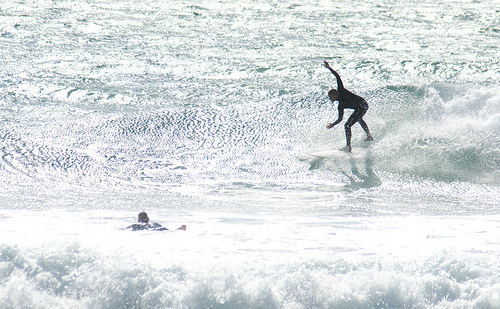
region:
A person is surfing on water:
[277, 35, 412, 166]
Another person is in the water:
[111, 195, 196, 255]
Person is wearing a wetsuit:
[295, 55, 400, 180]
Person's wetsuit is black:
[266, 52, 413, 174]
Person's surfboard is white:
[298, 135, 368, 172]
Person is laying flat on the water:
[108, 191, 220, 257]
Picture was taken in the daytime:
[5, 15, 495, 285]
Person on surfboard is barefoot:
[322, 125, 398, 167]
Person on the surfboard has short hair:
[317, 82, 343, 112]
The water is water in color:
[20, 221, 483, 304]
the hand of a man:
[319, 57, 333, 69]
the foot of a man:
[339, 141, 353, 154]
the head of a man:
[324, 85, 339, 105]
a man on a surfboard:
[319, 57, 382, 153]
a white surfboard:
[303, 146, 381, 162]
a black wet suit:
[329, 62, 382, 145]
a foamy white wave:
[0, 234, 499, 307]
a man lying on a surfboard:
[118, 210, 189, 235]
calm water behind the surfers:
[1, 0, 499, 62]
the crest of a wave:
[193, 73, 499, 100]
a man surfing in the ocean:
[277, 26, 431, 171]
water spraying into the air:
[398, 114, 444, 149]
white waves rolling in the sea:
[171, 269, 286, 303]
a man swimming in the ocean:
[126, 204, 176, 246]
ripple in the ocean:
[165, 100, 257, 136]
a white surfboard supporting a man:
[306, 150, 344, 162]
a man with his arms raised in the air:
[303, 56, 417, 161]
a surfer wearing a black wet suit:
[291, 51, 402, 174]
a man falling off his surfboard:
[306, 57, 373, 150]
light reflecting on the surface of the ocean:
[213, 234, 280, 274]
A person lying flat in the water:
[123, 205, 195, 245]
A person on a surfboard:
[308, 57, 375, 182]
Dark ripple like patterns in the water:
[1, 98, 294, 185]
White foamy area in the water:
[0, 245, 499, 307]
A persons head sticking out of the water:
[132, 208, 154, 224]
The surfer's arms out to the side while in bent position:
[311, 51, 346, 130]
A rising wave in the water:
[365, 68, 495, 194]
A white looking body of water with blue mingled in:
[0, 0, 499, 50]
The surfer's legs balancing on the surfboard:
[341, 107, 379, 159]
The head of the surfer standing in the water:
[326, 80, 343, 103]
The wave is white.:
[51, 240, 326, 297]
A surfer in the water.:
[125, 197, 202, 237]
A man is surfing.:
[289, 47, 397, 152]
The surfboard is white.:
[277, 130, 382, 165]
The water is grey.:
[98, 33, 267, 128]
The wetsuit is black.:
[340, 86, 361, 116]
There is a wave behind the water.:
[394, 81, 487, 178]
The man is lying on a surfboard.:
[118, 219, 187, 237]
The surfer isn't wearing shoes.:
[336, 132, 400, 152]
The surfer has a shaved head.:
[318, 74, 342, 109]